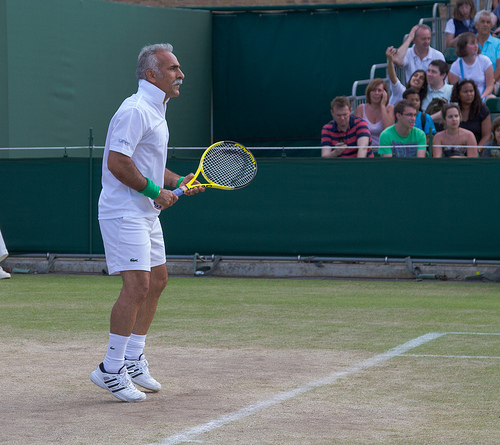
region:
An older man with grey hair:
[87, 40, 192, 410]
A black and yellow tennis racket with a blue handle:
[162, 135, 262, 195]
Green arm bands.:
[135, 165, 185, 200]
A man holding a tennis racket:
[82, 40, 254, 400]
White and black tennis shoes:
[85, 355, 160, 405]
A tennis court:
[0, 270, 495, 440]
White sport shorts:
[97, 210, 164, 271]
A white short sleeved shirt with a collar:
[95, 80, 166, 211]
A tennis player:
[74, 40, 263, 410]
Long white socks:
[104, 334, 146, 367]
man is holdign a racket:
[80, 20, 290, 414]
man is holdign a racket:
[57, 19, 270, 336]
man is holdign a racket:
[75, 33, 276, 245]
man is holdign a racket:
[75, 37, 258, 272]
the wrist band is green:
[121, 155, 167, 209]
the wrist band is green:
[114, 174, 172, 214]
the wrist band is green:
[140, 168, 170, 208]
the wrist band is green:
[125, 173, 170, 204]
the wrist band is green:
[127, 166, 170, 205]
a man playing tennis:
[86, 40, 258, 406]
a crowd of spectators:
[324, 10, 499, 160]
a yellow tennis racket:
[197, 143, 259, 190]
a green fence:
[2, 153, 498, 260]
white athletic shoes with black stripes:
[89, 353, 161, 403]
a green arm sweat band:
[139, 175, 164, 199]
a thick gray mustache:
[170, 77, 185, 85]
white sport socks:
[104, 329, 149, 371]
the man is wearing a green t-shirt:
[377, 100, 426, 158]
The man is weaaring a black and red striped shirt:
[322, 97, 372, 159]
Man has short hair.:
[131, 34, 202, 72]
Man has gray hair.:
[123, 33, 210, 79]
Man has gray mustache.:
[168, 73, 195, 86]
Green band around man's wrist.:
[136, 176, 173, 205]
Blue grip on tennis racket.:
[165, 183, 200, 210]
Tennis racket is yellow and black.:
[198, 135, 257, 196]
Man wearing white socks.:
[98, 333, 181, 366]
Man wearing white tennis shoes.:
[91, 355, 199, 395]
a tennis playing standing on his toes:
[88, 41, 257, 403]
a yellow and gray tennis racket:
[155, 138, 256, 208]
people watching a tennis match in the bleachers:
[319, 0, 499, 156]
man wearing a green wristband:
[140, 177, 160, 198]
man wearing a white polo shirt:
[95, 79, 170, 219]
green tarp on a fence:
[2, 157, 499, 262]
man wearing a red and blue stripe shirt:
[322, 115, 374, 154]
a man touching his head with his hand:
[393, 23, 445, 83]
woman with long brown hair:
[451, 78, 487, 120]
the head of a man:
[130, 36, 207, 106]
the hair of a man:
[137, 46, 176, 71]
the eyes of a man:
[165, 59, 185, 74]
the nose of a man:
[167, 65, 192, 77]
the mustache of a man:
[165, 76, 199, 88]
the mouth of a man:
[167, 81, 183, 89]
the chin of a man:
[170, 87, 188, 97]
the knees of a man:
[125, 266, 175, 308]